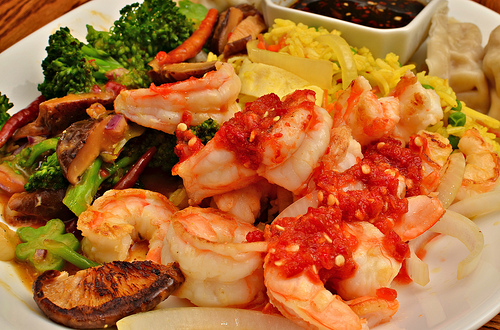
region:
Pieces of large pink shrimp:
[65, 59, 463, 328]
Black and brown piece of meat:
[32, 252, 184, 327]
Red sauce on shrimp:
[212, 81, 437, 298]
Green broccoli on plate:
[1, 2, 212, 224]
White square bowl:
[254, 0, 453, 80]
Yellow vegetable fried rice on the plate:
[237, 7, 498, 202]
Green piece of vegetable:
[12, 221, 104, 275]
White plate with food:
[1, 0, 497, 329]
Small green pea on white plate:
[448, 107, 464, 131]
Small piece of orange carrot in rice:
[254, 28, 290, 56]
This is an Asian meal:
[93, 16, 463, 296]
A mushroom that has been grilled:
[36, 251, 218, 321]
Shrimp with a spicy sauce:
[208, 112, 393, 312]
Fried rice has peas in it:
[271, 20, 468, 134]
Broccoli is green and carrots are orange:
[38, 5, 217, 168]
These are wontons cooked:
[418, 4, 493, 102]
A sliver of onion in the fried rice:
[319, 27, 367, 84]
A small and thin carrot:
[146, 9, 231, 62]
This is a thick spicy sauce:
[301, 0, 431, 73]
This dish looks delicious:
[101, 31, 451, 306]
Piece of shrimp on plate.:
[179, 221, 233, 293]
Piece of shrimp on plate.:
[276, 221, 347, 321]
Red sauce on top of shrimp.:
[277, 220, 339, 276]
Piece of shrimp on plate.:
[233, 110, 290, 157]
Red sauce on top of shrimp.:
[230, 98, 285, 152]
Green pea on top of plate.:
[435, 101, 475, 134]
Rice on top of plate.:
[294, 32, 311, 55]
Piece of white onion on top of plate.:
[322, 32, 362, 94]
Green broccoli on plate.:
[58, 35, 113, 84]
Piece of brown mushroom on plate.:
[57, 113, 94, 149]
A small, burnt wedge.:
[35, 255, 194, 329]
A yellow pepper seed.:
[332, 255, 346, 266]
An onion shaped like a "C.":
[406, 207, 483, 287]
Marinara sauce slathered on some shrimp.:
[295, 215, 322, 260]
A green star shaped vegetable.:
[13, 218, 83, 273]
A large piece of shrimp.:
[165, 95, 338, 195]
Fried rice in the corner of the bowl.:
[270, 18, 326, 59]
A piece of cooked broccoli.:
[36, 26, 118, 102]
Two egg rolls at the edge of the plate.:
[423, 12, 499, 110]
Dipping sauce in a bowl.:
[276, 1, 426, 33]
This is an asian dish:
[37, 90, 337, 280]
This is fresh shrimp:
[135, 91, 327, 278]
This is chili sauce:
[250, 221, 377, 323]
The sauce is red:
[232, 212, 379, 325]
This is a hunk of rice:
[275, 16, 291, 63]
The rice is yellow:
[268, 29, 382, 168]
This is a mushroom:
[63, 235, 135, 315]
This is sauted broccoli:
[68, 34, 130, 123]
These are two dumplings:
[445, 31, 497, 73]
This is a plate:
[139, 87, 378, 327]